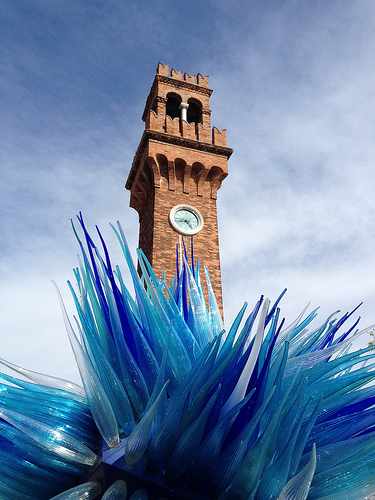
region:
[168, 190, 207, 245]
clock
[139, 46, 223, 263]
clock tower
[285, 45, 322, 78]
white clouds in blue sky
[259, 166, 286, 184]
white clouds in blue sky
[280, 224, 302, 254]
white clouds in blue sky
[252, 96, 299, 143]
white clouds in blue sky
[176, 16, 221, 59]
white clouds in blue sky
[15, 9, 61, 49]
white clouds in blue sky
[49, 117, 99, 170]
white clouds in blue sky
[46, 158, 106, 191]
white clouds in blue sky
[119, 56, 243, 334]
large brick tower with clock embedded in it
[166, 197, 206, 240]
clock embedded in large brick tower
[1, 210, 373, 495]
large blue flower in front of brick tower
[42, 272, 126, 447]
clear petal on large flower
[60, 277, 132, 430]
light blue petal on large flower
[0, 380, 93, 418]
light blue petal on large flower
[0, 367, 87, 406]
light blue petal on large flower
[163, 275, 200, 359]
light blue petal on large flower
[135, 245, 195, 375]
light blue petal on large flower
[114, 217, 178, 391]
light blue petal on large flower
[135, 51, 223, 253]
brown clock towe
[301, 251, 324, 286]
white clouds in blue sky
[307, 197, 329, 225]
white clouds in blue sky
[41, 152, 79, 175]
white clouds in blue sky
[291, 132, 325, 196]
white clouds in blue sky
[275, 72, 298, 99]
white clouds in blue sky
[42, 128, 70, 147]
white clouds in blue sky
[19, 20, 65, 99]
white clouds in blue sky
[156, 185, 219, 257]
the clock on a building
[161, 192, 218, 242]
the round clock on a building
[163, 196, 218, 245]
a round clock on a building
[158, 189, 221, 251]
the hands on a clock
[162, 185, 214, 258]
the big hand on a clock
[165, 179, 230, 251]
the little hand on a clock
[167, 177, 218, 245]
a big white clock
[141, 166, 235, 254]
a big clock on a building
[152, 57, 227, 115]
the top of a building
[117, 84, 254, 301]
a clock on top of a building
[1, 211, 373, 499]
unusual blue glass light fixture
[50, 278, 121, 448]
lightbulb shaped like an icicle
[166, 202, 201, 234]
outdoor clock in a tower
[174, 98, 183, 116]
white column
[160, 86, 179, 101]
arch in a tower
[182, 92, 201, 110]
arch in a tower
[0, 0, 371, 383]
cloudy sky behind a tower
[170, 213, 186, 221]
minute hand of a clock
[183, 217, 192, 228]
hour hand of a clock